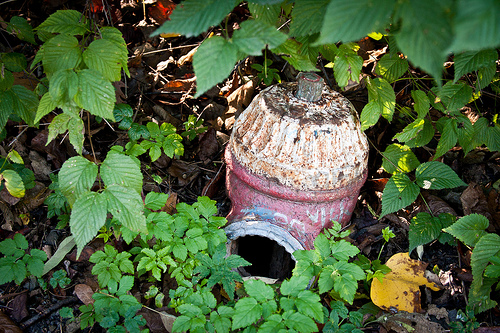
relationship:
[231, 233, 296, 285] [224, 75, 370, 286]
hole on hydrant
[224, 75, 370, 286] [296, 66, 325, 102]
hydrant has a bolt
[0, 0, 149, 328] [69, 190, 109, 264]
plant has grean leaves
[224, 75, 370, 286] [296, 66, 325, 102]
fire hydrant has a bolt on top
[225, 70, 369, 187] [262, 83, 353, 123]
top has dirt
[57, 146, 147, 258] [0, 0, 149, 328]
four leaves on plant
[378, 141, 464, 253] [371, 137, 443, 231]
leaves on a thin branch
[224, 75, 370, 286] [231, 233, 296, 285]
fire hydrant has a hole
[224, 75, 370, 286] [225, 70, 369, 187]
fire hydrant has a top part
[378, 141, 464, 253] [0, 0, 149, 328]
leaves of a plant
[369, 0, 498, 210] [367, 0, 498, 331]
sunlight on leaves